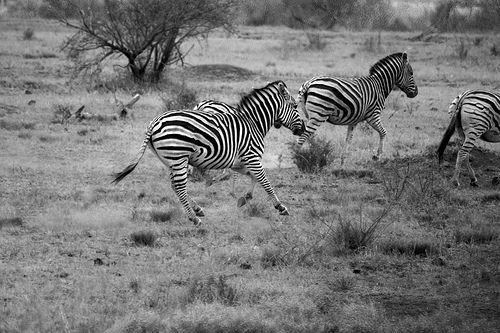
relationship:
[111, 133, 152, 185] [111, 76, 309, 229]
tail of zebra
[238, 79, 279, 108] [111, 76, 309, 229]
hair on zebra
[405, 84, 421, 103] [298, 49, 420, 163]
mouth of zebra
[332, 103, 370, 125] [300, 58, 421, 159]
stomach of zebra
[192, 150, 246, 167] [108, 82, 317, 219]
stomach of zebra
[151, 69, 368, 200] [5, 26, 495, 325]
zebras running field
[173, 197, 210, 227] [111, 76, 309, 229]
feet of zebra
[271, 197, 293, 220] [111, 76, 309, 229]
feet of zebra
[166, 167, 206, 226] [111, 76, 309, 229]
back legs of zebra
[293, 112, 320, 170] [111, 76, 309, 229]
back legs of zebra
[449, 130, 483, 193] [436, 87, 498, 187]
back legs of zebra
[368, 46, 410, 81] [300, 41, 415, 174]
front snout of zebra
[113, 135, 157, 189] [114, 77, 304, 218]
tail of zebras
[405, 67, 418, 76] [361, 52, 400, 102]
eye of zebra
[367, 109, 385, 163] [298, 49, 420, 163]
leg of zebra